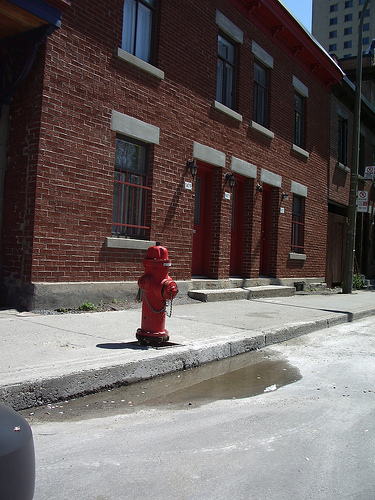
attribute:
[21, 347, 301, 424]
puddle — shallow, water, dirty, big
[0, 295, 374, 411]
sidewalk — concrete, long, cement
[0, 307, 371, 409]
step — concrete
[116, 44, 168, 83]
sill — concrete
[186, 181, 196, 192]
sign — white, black, small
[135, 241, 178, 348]
hydrant — red, painted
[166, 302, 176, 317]
chain — metal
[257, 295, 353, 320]
shadow — cast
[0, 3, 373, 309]
residence — brick, red, long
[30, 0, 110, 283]
wall — red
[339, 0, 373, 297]
pole — metal, tall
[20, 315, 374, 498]
street — gray, concrete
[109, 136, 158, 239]
window — protected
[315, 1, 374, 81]
building — tall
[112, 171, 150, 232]
bars — red, metal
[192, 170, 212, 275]
door — red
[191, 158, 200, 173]
light — black, outdoor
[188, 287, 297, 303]
steps — cement, concrete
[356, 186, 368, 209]
signs — strapped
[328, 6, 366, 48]
windows — square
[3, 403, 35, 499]
bumper — gray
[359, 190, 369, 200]
sign — red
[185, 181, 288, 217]
numbers — addresses